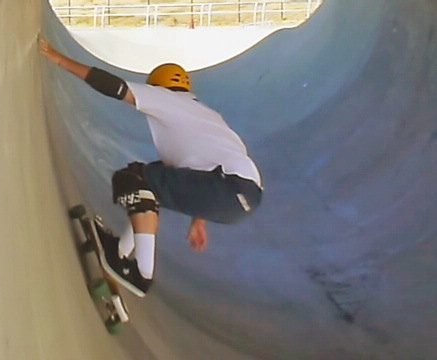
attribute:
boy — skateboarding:
[38, 35, 265, 329]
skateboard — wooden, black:
[72, 203, 129, 332]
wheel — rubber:
[68, 202, 86, 223]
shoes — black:
[89, 214, 155, 303]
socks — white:
[115, 220, 156, 282]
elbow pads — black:
[84, 65, 129, 101]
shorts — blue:
[144, 160, 264, 223]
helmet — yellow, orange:
[146, 62, 191, 92]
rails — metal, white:
[54, 2, 312, 27]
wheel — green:
[88, 279, 113, 302]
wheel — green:
[106, 315, 127, 339]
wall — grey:
[0, 1, 116, 359]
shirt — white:
[127, 82, 261, 190]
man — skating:
[127, 81, 262, 185]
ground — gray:
[70, 23, 305, 73]